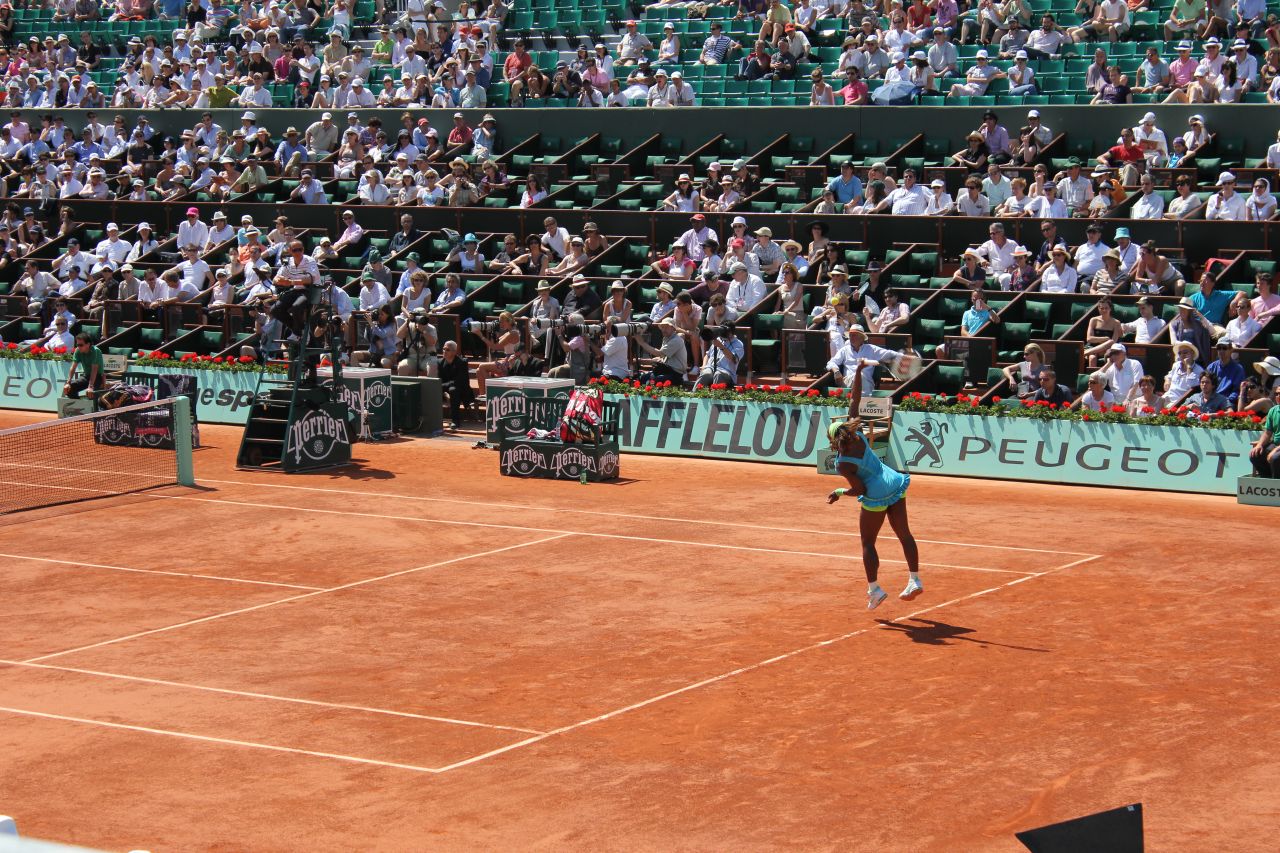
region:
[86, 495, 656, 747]
a tennis court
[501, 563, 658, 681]
the court is brown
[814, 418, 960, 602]
a tennis player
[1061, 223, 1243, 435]
people in the audience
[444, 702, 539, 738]
a line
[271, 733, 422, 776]
a white line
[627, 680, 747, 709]
a line on the tennis court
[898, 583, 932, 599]
tennis player is wearing shoes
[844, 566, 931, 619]
Woman wearing shoes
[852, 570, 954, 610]
Woman is wearing shoes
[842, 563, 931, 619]
Woman wearing white shoes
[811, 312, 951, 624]
Woman is playing tennis on a clay court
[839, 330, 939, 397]
Woman is holding a tennis racket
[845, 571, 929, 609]
woman wearing white shoes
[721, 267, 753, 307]
man wearing a white shirt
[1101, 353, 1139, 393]
man wearing a white shirt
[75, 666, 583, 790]
white lines on the court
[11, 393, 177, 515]
net on the tennis court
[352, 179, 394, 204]
man wearing a white shirt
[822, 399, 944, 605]
The female player in action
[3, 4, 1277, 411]
A crowd of tennis spectators.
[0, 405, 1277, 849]
The brown, white marked tennis court.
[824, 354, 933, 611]
The tennis player wearing blue.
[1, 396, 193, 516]
The mounted tennis goal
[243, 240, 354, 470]
The chair umpire in the tennis court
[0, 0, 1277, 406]
The multiple green chairs on the dais in the tennis court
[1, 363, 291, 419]
The green advertisement board on the left.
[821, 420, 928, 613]
the tennis player jumping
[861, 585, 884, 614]
the white shoe of the tennis player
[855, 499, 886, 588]
the leg of the tennis player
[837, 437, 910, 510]
the blue dress of the tennis player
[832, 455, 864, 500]
the arm of the tennis player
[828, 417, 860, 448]
the head of the tennis player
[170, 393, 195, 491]
the green net pole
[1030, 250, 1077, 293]
A person is sitting down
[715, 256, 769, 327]
A person is sitting down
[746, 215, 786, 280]
A person is sitting down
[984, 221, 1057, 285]
A person is sitting down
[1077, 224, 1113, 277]
A person is sitting down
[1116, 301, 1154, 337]
A person is sitting down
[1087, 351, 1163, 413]
A person is sitting down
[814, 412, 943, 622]
Athlete jumps off the ground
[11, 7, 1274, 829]
Audience watches the tennis match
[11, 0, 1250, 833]
Audience cheers on the tennis player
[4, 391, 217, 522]
Black and white net on a tennis court post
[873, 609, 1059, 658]
Shadow of woman serving tennisball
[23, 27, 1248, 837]
this is a sporting event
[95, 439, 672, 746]
this is a tennis court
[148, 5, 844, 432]
these are a bunch of fans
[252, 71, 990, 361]
the fans are in the stands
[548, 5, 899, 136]
the chairs are green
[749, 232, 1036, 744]
this is a tennis player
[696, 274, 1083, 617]
the player is jumping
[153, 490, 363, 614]
the court is clay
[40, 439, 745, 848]
the court is red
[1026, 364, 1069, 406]
spectator watching tennis game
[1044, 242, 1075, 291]
spectator watching tennis game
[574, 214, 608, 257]
spectator watching tennis game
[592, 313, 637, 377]
spectator watching tennis game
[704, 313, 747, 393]
spectator watching tennis game